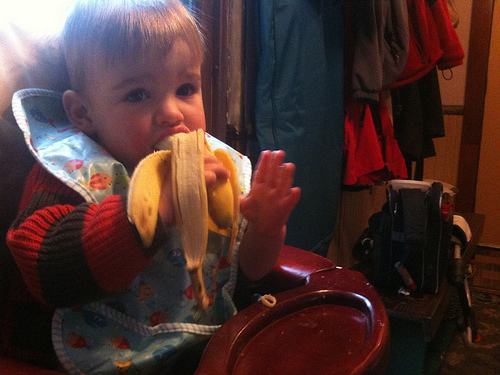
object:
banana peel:
[126, 127, 242, 311]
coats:
[388, 0, 465, 90]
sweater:
[5, 158, 173, 310]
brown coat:
[339, 0, 407, 104]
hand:
[237, 148, 304, 223]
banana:
[127, 127, 243, 310]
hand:
[150, 150, 230, 223]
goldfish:
[89, 172, 115, 192]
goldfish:
[107, 333, 133, 350]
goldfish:
[63, 157, 83, 173]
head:
[61, 1, 208, 169]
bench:
[347, 207, 487, 373]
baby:
[5, 0, 300, 374]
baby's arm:
[230, 148, 302, 307]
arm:
[5, 152, 231, 308]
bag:
[252, 2, 351, 262]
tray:
[197, 275, 392, 373]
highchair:
[3, 244, 392, 373]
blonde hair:
[58, 0, 209, 93]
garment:
[342, 85, 408, 187]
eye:
[176, 83, 198, 97]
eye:
[121, 86, 148, 103]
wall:
[195, 1, 496, 257]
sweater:
[7, 158, 275, 311]